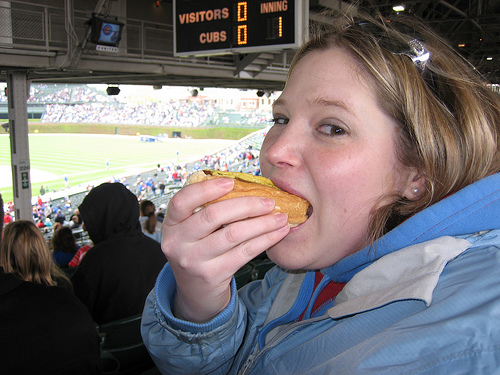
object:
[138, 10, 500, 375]
woman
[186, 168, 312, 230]
hot dog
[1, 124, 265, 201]
baseball game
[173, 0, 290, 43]
screen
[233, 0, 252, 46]
scores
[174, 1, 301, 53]
scoreboard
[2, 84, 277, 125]
spectators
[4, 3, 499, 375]
stadium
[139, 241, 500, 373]
jacket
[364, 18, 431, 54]
sunglasses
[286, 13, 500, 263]
hair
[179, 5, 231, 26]
word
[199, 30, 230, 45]
word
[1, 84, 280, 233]
background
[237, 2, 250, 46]
number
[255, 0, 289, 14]
word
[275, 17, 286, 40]
number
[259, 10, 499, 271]
head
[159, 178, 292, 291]
hand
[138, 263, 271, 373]
sleeve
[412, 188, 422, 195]
earring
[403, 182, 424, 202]
earlobe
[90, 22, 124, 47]
tv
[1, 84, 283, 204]
distance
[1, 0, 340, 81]
wall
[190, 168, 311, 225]
bun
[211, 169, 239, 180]
mustard